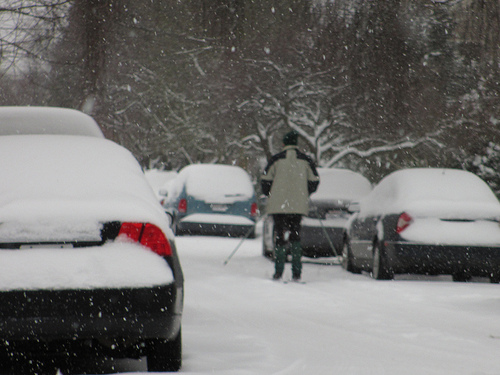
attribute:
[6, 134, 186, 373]
car — black, snow-covered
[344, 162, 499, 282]
car — snow-covered, dark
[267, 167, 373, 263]
car — snow-covered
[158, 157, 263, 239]
car — snow-covered, blue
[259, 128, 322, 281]
person — snow shoes, skiing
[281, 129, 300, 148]
hat — dark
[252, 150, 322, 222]
coat — gray, black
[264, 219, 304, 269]
pants — black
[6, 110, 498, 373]
snow — white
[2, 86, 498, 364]
snow — white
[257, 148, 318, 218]
coat — black, gray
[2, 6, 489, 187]
trees — leafless, snowy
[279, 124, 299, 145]
hat — black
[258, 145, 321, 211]
coat — grey and black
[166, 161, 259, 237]
car — blue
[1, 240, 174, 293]
snow — black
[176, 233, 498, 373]
ground — snow covered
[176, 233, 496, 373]
snow — white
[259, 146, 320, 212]
top — brown